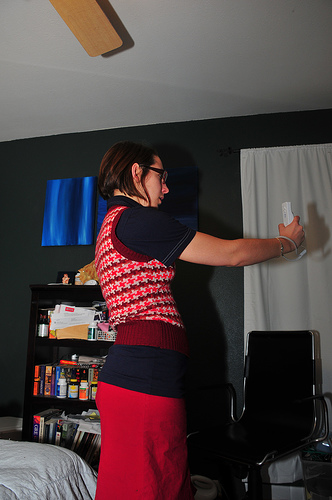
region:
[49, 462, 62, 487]
the blanket is white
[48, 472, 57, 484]
the blanket is white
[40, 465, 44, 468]
the blanket is white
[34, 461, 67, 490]
the blanket is white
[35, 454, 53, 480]
the blanket is white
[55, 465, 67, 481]
the blanket is white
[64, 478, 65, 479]
the blanket is white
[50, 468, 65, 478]
the blanket is white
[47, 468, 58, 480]
the blanket is white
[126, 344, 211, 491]
a woman in red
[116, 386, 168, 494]
a woman in red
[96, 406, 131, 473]
a woman in red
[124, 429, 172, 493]
a woman in red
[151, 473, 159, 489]
a woman in red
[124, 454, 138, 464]
a woman in red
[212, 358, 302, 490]
a black chair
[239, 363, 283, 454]
a black chair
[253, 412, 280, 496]
a black chair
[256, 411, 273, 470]
a black chair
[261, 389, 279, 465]
a black chair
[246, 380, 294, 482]
a black chair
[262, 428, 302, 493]
a black chair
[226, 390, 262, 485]
a black chair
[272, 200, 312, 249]
White nintendo wii remote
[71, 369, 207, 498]
Bright red dress on girl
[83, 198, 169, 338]
Red and white knitted vest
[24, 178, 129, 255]
Blue painting on shelf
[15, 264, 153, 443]
Black shelf with books on it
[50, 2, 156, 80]
Brown wooden ceiling fan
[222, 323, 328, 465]
Black and silver chair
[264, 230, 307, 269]
Bracelet on girl's arm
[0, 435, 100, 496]
White cotton bed spread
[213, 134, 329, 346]
White cotton curtains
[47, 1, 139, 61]
Light brown stained ceiling fan blade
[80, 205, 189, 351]
Young lady is wearing a hideously tacky sweater vest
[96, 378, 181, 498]
Girl is wearing a bright red secret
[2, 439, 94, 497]
Light blue blanket on woman's bed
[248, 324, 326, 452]
Large black and chrome office chair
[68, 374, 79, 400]
Bottle of vitamin supplements with yellow top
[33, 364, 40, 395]
Neon orange rectangular object on medium shelf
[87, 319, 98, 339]
Green and white bottle of white out on top of shelf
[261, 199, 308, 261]
Girl holding Wii video game controller in right hand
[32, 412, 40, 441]
Red, white, and blue spine of book on bottom shelf